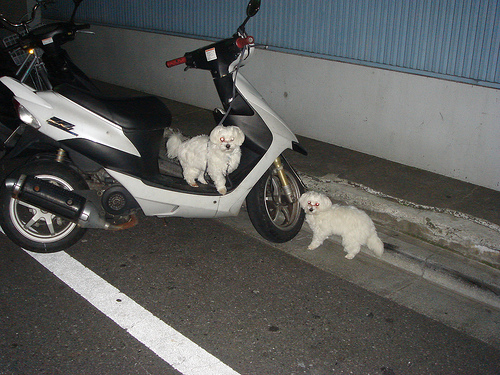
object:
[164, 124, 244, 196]
dog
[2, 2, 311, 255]
bike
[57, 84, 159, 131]
seat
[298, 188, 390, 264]
dog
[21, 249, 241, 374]
line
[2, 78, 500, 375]
ground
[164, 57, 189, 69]
handles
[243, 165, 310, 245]
tire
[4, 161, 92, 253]
tire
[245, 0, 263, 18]
mirror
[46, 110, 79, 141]
label